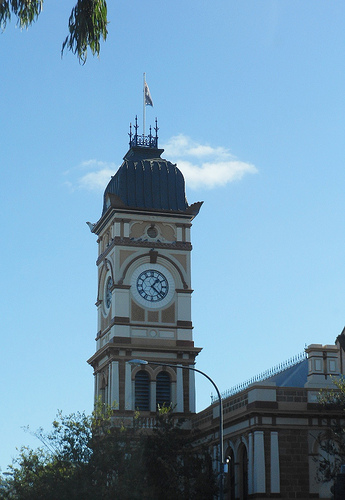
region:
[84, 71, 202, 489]
A tall clock tower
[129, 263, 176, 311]
the face of a tall clock tower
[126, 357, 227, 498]
A streetlight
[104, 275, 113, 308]
the face of a tall clock tower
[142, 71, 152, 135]
A flag hanging on a pole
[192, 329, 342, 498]
A large building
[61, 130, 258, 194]
Clouds in a mostly-clear sky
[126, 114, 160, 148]
Decorative spikes atop a clock tower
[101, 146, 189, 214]
Blue roof of a clock tower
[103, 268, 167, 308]
clock face on a clock tower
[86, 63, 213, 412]
A tan colored clock tower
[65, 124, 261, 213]
One cloud is in the sky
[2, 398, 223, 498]
A tree is in the foreground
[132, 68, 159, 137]
A flag is on top of the clock tower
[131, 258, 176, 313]
The clock is white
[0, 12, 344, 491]
Photo was taken outdoors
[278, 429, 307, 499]
Front angle of the building is made of brick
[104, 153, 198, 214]
Top of the clock tower is dark blue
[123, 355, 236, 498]
A street light is in the foreground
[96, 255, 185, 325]
Two clocks on two different sides of the building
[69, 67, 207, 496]
Tall clock tower with tan coloring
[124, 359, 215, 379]
Gray metal street light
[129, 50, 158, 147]
Flag on top of tower hanging limp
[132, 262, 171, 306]
Black and white analog clock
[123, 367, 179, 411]
Dark windows in light colored tower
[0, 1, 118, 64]
Green leaves in the sky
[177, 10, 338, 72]
Clear light blue sky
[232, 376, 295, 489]
White columns on the corner of a dark brick building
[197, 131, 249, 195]
Fluffy cloud in the blue sky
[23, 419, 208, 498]
Branches of a tree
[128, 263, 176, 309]
clock on the building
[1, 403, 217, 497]
dark tree top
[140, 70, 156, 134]
flag on the top of the tower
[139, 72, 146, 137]
skinny gray flag pole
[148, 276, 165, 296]
two perpendicular clock hands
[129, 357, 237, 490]
light post that is not turned on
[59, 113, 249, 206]
puffy white clouds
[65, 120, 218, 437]
tall clock tower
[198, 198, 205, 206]
sharp corner of the building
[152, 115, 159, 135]
sharp decorative pole on the top of the building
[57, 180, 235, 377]
tower with a clock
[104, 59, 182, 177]
tower with a steeple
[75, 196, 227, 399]
decorative wood trim on tower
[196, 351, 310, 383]
spikes along the top of building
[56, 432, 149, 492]
green tree in-front of building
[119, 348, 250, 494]
street lamp next to building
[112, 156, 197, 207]
metal top to the tower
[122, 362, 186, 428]
windows with arches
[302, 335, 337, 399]
chimney on tops of buildings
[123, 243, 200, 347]
clock tower with trim